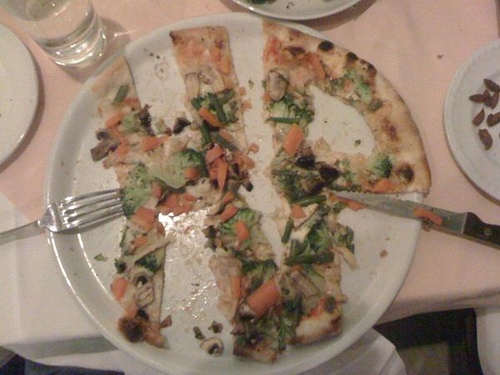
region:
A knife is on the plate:
[336, 184, 492, 247]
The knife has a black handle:
[333, 178, 492, 247]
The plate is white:
[53, 19, 425, 366]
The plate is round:
[53, 20, 424, 367]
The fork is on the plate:
[14, 181, 121, 256]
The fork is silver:
[3, 174, 128, 262]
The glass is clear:
[13, 2, 110, 79]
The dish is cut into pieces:
[99, 17, 404, 354]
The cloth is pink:
[0, 2, 490, 296]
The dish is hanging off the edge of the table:
[36, 32, 414, 372]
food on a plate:
[24, 26, 447, 367]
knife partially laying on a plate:
[332, 178, 493, 255]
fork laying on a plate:
[0, 191, 140, 266]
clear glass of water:
[14, 0, 121, 80]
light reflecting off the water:
[68, 40, 92, 59]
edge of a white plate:
[2, 24, 44, 169]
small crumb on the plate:
[376, 245, 390, 262]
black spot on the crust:
[315, 35, 335, 56]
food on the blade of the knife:
[405, 206, 446, 223]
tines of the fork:
[64, 188, 136, 231]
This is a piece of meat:
[121, 301, 179, 351]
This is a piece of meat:
[116, 265, 156, 309]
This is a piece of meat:
[132, 202, 165, 254]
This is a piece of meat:
[153, 182, 189, 218]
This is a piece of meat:
[94, 112, 136, 160]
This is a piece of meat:
[138, 129, 175, 160]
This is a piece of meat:
[183, 160, 200, 181]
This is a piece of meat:
[186, 98, 232, 130]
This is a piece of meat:
[198, 150, 230, 188]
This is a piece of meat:
[241, 280, 296, 325]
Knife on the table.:
[330, 175, 499, 252]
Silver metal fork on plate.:
[2, 180, 119, 249]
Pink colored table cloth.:
[391, 0, 492, 36]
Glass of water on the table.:
[5, 1, 125, 66]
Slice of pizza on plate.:
[259, 23, 427, 199]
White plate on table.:
[1, 21, 45, 178]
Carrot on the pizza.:
[247, 278, 290, 323]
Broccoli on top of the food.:
[117, 163, 154, 224]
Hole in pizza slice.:
[284, 68, 382, 183]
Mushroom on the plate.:
[89, 124, 125, 160]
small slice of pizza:
[81, 49, 167, 216]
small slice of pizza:
[104, 198, 182, 361]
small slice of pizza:
[165, 14, 255, 197]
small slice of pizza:
[192, 187, 293, 364]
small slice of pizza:
[271, 183, 367, 349]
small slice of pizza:
[264, 16, 435, 206]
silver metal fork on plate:
[0, 187, 131, 239]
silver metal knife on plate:
[330, 183, 498, 254]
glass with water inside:
[5, 0, 119, 76]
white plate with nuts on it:
[440, 30, 499, 212]